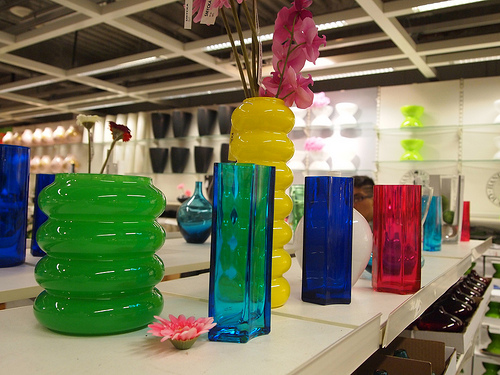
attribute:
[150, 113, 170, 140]
vase — black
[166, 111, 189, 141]
vase — black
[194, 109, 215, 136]
vase — black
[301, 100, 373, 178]
vases — white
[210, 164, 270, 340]
glass vase — tall, blue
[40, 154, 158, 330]
vase — green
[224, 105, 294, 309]
vase — tall, yellow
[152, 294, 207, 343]
flower — plastic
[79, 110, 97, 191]
flower — white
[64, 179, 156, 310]
vase — green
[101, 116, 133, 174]
flower — RED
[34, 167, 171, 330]
vase — GREEN, colorful, glass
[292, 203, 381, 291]
vase — white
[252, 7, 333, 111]
flower — pink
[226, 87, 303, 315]
vase — yellow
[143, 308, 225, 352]
flower — small, pink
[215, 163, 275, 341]
vase — clear blue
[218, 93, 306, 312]
vase — yellow, colorful, glass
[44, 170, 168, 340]
vase — green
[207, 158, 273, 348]
vase — blue, clear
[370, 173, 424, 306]
vase — red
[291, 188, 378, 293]
vase — white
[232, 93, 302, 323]
vase — yellow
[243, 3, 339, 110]
flower — pink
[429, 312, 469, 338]
light bulb — small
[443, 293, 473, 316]
light bulb — small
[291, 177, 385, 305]
vase — white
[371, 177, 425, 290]
vase — red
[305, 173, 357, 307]
vase — blue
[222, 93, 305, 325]
vase — yellow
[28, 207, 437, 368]
table — white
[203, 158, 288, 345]
vase — colorful, glass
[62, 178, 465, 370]
table — white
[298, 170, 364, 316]
vase — colorful, glass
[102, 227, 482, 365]
table — white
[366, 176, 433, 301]
vase — colorful, glass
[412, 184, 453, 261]
vase — glass, colorful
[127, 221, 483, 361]
table — white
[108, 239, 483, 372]
table — white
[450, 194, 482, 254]
vase — colorful, glass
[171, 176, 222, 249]
vase — glass, colorful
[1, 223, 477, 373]
table — white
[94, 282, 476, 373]
table — white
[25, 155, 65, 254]
vase — colorful, glass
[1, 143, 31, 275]
vase — glass, colorful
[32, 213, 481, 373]
table — white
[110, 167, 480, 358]
table — white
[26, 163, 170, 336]
vase — looks like four tubes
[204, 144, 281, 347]
vase — clear, square, blue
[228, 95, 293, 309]
vase — tall, yellow, tubed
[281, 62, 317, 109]
flower — pink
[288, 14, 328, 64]
flower — pink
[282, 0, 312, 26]
flower — pink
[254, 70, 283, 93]
flower — pink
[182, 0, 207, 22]
flower — pink